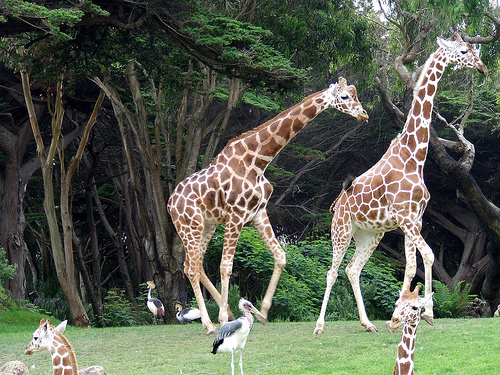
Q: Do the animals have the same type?
A: No, there are both giraffes and birds.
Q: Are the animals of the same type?
A: No, there are both giraffes and birds.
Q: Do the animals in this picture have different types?
A: Yes, they are giraffes and birds.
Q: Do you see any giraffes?
A: Yes, there is a giraffe.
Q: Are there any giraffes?
A: Yes, there is a giraffe.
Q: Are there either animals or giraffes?
A: Yes, there is a giraffe.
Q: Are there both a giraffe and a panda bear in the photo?
A: No, there is a giraffe but no panda bears.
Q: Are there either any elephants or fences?
A: No, there are no fences or elephants.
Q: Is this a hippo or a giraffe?
A: This is a giraffe.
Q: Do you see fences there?
A: No, there are no fences.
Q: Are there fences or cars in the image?
A: No, there are no fences or cars.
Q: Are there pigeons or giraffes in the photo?
A: Yes, there is a giraffe.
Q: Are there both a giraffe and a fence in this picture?
A: No, there is a giraffe but no fences.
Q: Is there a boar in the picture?
A: No, there are no boars.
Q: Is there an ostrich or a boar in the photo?
A: No, there are no boars or ostriches.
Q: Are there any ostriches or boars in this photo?
A: No, there are no boars or ostriches.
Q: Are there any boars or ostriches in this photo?
A: No, there are no boars or ostriches.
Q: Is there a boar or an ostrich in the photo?
A: No, there are no boars or ostriches.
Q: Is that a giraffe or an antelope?
A: That is a giraffe.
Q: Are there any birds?
A: Yes, there is a bird.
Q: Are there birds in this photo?
A: Yes, there is a bird.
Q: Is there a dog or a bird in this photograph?
A: Yes, there is a bird.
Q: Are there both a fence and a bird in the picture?
A: No, there is a bird but no fences.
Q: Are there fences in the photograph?
A: No, there are no fences.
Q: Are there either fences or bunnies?
A: No, there are no fences or bunnies.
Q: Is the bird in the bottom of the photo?
A: Yes, the bird is in the bottom of the image.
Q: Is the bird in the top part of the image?
A: No, the bird is in the bottom of the image.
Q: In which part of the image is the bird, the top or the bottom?
A: The bird is in the bottom of the image.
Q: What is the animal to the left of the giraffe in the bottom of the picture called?
A: The animal is a bird.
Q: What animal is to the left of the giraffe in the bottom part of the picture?
A: The animal is a bird.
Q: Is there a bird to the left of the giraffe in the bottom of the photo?
A: Yes, there is a bird to the left of the giraffe.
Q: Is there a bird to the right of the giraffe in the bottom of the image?
A: No, the bird is to the left of the giraffe.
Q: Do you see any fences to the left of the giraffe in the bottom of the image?
A: No, there is a bird to the left of the giraffe.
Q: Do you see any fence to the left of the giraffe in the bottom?
A: No, there is a bird to the left of the giraffe.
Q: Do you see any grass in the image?
A: Yes, there is grass.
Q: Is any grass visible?
A: Yes, there is grass.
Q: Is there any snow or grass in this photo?
A: Yes, there is grass.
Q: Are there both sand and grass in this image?
A: No, there is grass but no sand.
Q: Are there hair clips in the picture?
A: No, there are no hair clips.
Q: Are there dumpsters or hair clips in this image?
A: No, there are no hair clips or dumpsters.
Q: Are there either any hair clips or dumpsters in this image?
A: No, there are no hair clips or dumpsters.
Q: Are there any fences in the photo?
A: No, there are no fences.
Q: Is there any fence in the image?
A: No, there are no fences.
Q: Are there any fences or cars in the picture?
A: No, there are no fences or cars.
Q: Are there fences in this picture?
A: No, there are no fences.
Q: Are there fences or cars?
A: No, there are no fences or cars.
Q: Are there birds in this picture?
A: Yes, there is a bird.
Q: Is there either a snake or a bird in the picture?
A: Yes, there is a bird.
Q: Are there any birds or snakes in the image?
A: Yes, there is a bird.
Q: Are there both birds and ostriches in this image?
A: No, there is a bird but no ostriches.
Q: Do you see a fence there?
A: No, there are no fences.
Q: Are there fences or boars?
A: No, there are no fences or boars.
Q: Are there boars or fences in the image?
A: No, there are no fences or boars.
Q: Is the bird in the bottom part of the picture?
A: Yes, the bird is in the bottom of the image.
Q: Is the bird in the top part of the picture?
A: No, the bird is in the bottom of the image.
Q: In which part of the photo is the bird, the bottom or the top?
A: The bird is in the bottom of the image.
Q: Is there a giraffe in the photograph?
A: Yes, there is a giraffe.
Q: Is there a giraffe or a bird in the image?
A: Yes, there is a giraffe.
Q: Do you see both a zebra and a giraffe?
A: No, there is a giraffe but no zebras.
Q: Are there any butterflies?
A: No, there are no butterflies.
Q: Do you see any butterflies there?
A: No, there are no butterflies.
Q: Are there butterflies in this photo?
A: No, there are no butterflies.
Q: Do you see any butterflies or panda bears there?
A: No, there are no butterflies or panda bears.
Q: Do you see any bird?
A: Yes, there is a bird.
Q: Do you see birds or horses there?
A: Yes, there is a bird.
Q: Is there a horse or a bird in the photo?
A: Yes, there is a bird.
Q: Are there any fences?
A: No, there are no fences.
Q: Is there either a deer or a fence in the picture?
A: No, there are no fences or deer.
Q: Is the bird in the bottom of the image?
A: Yes, the bird is in the bottom of the image.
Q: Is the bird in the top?
A: No, the bird is in the bottom of the image.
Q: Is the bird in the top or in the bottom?
A: The bird is in the bottom of the image.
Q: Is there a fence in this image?
A: No, there are no fences.